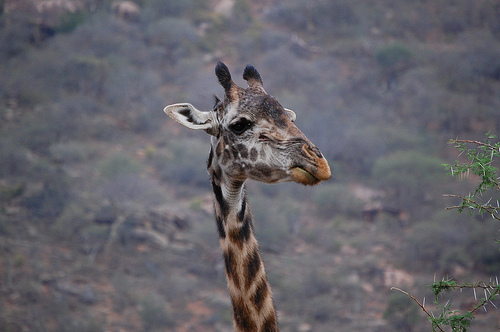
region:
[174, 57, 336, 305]
This animal is a giraffe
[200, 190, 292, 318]
The giraffe has a long neck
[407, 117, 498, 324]
A few tree branches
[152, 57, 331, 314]
The giraffe is stationary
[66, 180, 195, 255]
There are stick laying on the ground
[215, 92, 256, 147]
You can only see the giraffe's right eye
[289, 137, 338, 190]
The giraffe's mouth is closed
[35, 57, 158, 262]
There are many patches of green on the ground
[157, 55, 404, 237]
The giraffe is getting ready to eat the tree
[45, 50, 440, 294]
The image was taken outdoors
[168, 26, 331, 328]
a horned giraffe.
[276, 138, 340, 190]
the mouth of a giraffe.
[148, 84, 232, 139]
the right ear of a giraffe.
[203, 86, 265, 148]
the right eye of a giraffe.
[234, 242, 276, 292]
a spot on a giraffe.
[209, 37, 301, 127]
the forehed of a giraffe.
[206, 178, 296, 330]
a long giraffe neck.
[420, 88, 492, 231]
a tree with lots of leaves.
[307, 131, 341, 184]
a nose on a giraffe.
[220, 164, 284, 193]
a throat of a giraffe.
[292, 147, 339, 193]
Brown nose on a Giraffe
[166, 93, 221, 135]
Perked ears on giraffe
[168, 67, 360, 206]
Giraffe looking forward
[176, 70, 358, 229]
Giraffe in front of trees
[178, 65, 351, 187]
Giraffe looking at trees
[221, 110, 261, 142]
Giraffe with black eyes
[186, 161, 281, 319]
Giraffe with a long black neck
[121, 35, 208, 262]
Trees behind a Giraffe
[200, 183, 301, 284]
Giraffe with a skinny neck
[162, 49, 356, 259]
Giraffe looking towards tree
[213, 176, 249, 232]
white patch on upper throat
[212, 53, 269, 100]
a giraffes horns or ossicones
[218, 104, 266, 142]
large soft looking dark eye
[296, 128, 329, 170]
rather flat nose lays on top of snout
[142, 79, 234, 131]
an ear that is white and black inside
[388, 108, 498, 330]
needle like leaves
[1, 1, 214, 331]
rocky terraine in rear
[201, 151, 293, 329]
thin spotted upper neck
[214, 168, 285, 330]
wider cream colored separation of the spots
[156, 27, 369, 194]
a giraffe glances off to his left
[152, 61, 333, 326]
a big tall giraffe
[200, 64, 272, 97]
two black tipped giraffe horns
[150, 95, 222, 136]
a giraffe ear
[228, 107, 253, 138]
a very dark giraffe eye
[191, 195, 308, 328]
some black orange and peach colored giraffe spots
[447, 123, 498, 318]
some thorny plant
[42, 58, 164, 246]
some mountain terrain in the distance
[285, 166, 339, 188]
a giraffe mouth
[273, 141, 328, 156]
a giraffe nose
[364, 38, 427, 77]
a tree in the distance